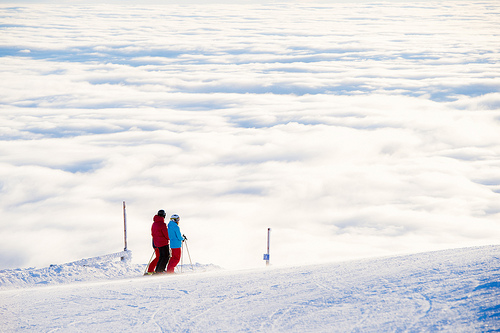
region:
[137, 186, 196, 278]
two skiers at start of ski run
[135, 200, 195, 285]
a couple at the start of the run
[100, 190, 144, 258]
a post on top of the mountain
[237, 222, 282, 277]
a post on top of the mountain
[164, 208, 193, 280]
Woman in a blue coat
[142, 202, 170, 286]
man in a red coat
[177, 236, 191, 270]
ski poles in the skier's hands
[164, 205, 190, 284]
woman in red pants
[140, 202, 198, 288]
couple about to start skiing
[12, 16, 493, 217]
clouds as far as one can see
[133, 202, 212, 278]
people skiing on the snow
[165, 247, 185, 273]
bright red snow pants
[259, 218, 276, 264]
pole sticking out of the snow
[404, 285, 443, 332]
tracks in the snow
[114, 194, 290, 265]
two skinny poles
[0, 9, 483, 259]
puffy white clouds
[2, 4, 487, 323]
people on a mountain so high that they are above the clouds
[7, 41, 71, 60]
bit of blue sky peaking through the clouds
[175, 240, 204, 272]
two skinny ski poles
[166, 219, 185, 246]
bright blue winter jacket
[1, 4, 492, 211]
A sky full of thick clouds.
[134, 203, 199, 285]
Two people about to ski.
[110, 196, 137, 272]
A pole sticking up from the ground.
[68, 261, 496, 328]
Ground completely covered in snow.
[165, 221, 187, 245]
A blue jacket with long sleeves.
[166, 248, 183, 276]
A pair of red pants.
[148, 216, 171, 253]
A red jacket with long sleeves.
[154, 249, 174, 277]
A pair of black pants.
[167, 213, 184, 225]
A helmet on someone's head.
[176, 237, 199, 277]
Poles to ski with.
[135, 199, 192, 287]
two people standing on top of mountain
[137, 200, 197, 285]
two people wearing warm clothign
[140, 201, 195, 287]
two people wearing ski outfits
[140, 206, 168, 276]
person wearing red ski jacket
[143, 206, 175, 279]
person wearing black ski hat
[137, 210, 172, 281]
person wearing black ski pants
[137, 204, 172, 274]
tall person holding ski poles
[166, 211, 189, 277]
person wearing light blue jacket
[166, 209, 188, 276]
person wearing red ski pants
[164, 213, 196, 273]
shorter person holding ski poles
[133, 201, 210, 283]
group of people skiing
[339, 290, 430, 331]
thin tracks in the snow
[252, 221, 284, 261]
pole sticking out of the snow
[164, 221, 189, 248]
bright blue jacket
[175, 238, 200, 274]
two thin ski poles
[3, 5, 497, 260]
top view of large fluffy clouds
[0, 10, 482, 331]
people on a mountaintop so high that they are above the clouds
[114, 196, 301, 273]
two poles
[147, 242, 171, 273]
black snow pants